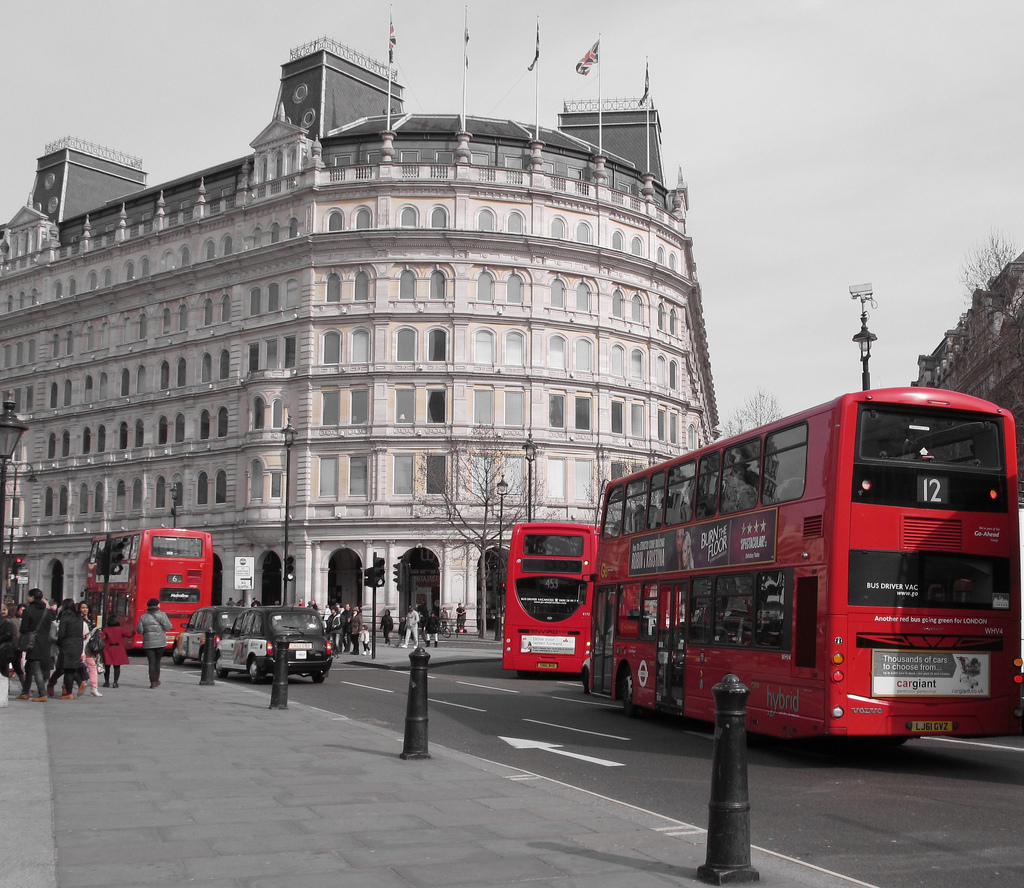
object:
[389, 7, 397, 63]
flags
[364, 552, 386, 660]
light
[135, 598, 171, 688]
people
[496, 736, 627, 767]
arrow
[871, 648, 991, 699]
sign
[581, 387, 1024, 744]
bus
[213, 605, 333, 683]
car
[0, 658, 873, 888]
sidewalk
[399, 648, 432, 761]
pillars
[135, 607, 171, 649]
jacket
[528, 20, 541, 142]
poles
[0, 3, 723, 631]
building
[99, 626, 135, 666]
coat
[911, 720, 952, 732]
plate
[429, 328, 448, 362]
window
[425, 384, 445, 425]
window